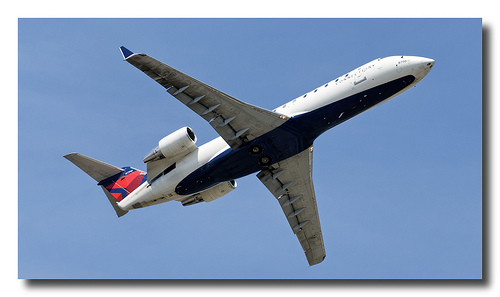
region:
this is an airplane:
[71, 32, 454, 270]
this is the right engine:
[113, 102, 218, 165]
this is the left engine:
[174, 165, 248, 217]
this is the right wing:
[108, 28, 306, 155]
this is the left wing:
[240, 135, 350, 270]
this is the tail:
[54, 136, 161, 233]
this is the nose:
[387, 45, 462, 88]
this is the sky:
[323, 180, 355, 206]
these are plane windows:
[233, 60, 370, 127]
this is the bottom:
[183, 79, 414, 204]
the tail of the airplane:
[52, 136, 184, 245]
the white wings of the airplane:
[121, 30, 359, 272]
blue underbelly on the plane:
[160, 47, 422, 205]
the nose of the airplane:
[395, 35, 448, 110]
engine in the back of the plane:
[131, 121, 223, 166]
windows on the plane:
[277, 69, 359, 104]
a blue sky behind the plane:
[23, 55, 114, 116]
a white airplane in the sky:
[57, 13, 464, 264]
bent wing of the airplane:
[107, 26, 173, 86]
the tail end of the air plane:
[37, 110, 263, 245]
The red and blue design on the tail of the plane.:
[97, 157, 141, 194]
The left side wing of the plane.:
[126, 35, 280, 134]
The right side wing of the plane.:
[271, 141, 340, 273]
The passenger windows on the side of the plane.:
[269, 65, 361, 102]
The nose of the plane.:
[415, 54, 437, 69]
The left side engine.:
[133, 122, 200, 158]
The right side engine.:
[179, 168, 241, 208]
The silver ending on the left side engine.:
[140, 145, 162, 162]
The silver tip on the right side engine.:
[183, 192, 200, 204]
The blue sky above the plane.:
[22, 27, 472, 266]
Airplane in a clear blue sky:
[53, 39, 466, 267]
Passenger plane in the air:
[57, 41, 442, 263]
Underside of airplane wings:
[110, 38, 333, 268]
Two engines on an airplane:
[135, 125, 237, 206]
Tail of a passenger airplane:
[52, 137, 138, 212]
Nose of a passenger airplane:
[380, 47, 440, 107]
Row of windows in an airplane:
[278, 67, 356, 98]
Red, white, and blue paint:
[92, 150, 152, 222]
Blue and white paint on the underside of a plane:
[157, 73, 432, 193]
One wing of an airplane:
[106, 42, 289, 141]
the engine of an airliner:
[143, 123, 196, 168]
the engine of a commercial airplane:
[180, 175, 235, 209]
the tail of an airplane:
[62, 148, 149, 218]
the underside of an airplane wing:
[118, 45, 280, 137]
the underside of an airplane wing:
[253, 148, 325, 268]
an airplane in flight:
[58, 40, 446, 267]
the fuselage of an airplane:
[280, 53, 435, 133]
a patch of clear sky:
[18, 18, 117, 149]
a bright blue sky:
[344, 133, 484, 281]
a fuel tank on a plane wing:
[277, 178, 294, 195]